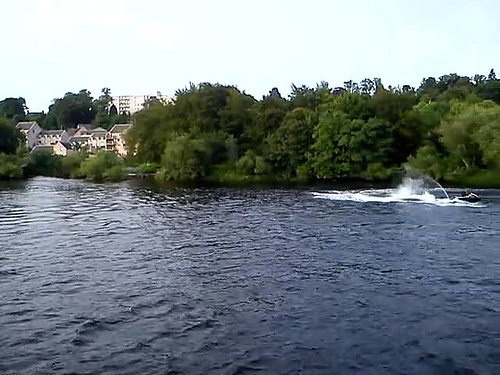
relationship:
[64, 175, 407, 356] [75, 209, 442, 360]
water in lake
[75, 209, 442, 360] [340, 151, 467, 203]
lake has jetski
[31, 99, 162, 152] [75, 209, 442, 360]
building by lake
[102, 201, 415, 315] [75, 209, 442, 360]
ripple in lake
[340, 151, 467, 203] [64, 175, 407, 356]
jetski in water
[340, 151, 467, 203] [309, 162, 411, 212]
jetski has wave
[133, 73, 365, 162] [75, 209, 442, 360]
trees by lake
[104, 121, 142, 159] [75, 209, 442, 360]
building by lake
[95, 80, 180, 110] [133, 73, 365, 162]
hotel by trees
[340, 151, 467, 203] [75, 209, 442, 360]
jetski in lake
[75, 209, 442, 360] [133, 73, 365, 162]
lake by trees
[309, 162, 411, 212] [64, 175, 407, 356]
wave in water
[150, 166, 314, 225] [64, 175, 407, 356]
stream of water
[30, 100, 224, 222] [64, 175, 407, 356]
houses near water